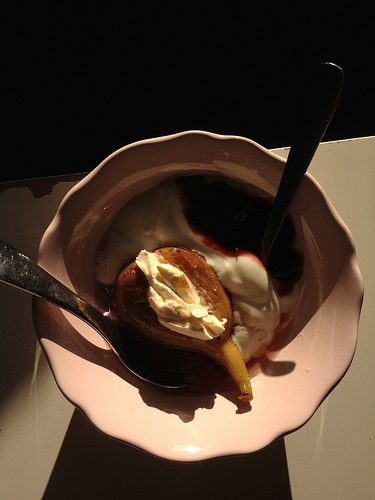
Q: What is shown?
A: Food.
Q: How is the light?
A: Dim.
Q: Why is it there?
A: To be eaten.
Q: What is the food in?
A: Bowl.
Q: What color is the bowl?
A: Pink.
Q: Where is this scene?
A: Table.